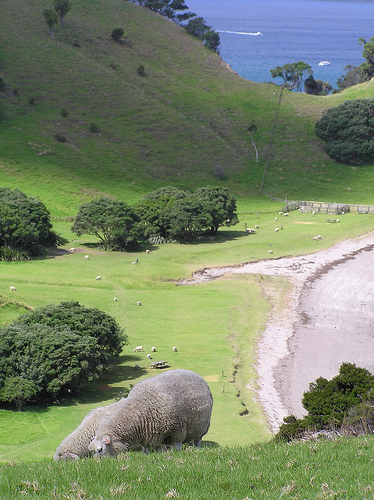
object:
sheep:
[96, 276, 101, 280]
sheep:
[10, 286, 17, 291]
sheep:
[134, 346, 143, 352]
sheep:
[172, 346, 176, 352]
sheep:
[147, 354, 150, 359]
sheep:
[151, 347, 156, 352]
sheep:
[246, 228, 255, 233]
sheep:
[337, 218, 340, 222]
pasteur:
[0, 199, 374, 460]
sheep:
[53, 397, 126, 460]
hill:
[0, 424, 374, 498]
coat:
[123, 384, 202, 436]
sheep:
[282, 200, 373, 214]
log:
[252, 141, 259, 163]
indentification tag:
[101, 433, 110, 444]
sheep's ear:
[101, 433, 111, 445]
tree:
[0, 183, 70, 261]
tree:
[71, 196, 156, 251]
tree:
[160, 195, 228, 242]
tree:
[193, 185, 239, 232]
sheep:
[88, 370, 213, 459]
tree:
[276, 361, 374, 441]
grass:
[186, 447, 356, 481]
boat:
[257, 30, 262, 35]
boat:
[319, 59, 331, 65]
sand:
[272, 257, 362, 393]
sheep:
[96, 276, 100, 280]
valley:
[3, 0, 374, 499]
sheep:
[85, 255, 89, 259]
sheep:
[146, 250, 149, 253]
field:
[3, 62, 365, 349]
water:
[155, 0, 373, 95]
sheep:
[69, 248, 75, 253]